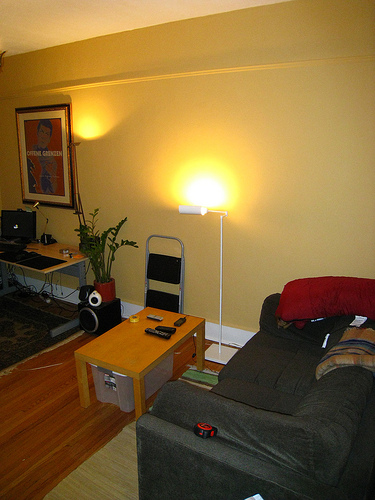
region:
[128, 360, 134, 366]
part of a table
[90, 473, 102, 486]
part of a carpet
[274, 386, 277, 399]
part of a pillow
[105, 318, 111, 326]
part of a speaker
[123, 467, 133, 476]
part of a floor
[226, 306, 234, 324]
part of a wall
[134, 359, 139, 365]
edge of a table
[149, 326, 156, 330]
part of a remote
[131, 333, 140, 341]
edge of a table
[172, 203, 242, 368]
a white floor lamp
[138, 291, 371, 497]
a dark grey couch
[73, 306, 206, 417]
a light brown table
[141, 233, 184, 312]
a folded up step ladder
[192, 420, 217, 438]
a black and red measuring tape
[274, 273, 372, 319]
a red throw pillow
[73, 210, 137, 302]
a green potted plant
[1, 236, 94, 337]
a light brown wooden desk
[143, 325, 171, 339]
a black remote control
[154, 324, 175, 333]
a black remote control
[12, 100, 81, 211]
Picture hanging on the wall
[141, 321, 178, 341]
Remote controllers of the TV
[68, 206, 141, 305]
A green planet in the room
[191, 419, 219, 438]
A red and black measuring tape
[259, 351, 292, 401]
Part of the couch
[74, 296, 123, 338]
A speaker on the ground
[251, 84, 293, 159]
Part of the wall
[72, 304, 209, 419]
A table in the room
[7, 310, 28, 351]
Part of the carpet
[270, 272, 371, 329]
A red blanket on the couch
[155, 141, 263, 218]
a light is shining on the wall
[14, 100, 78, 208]
a frame is hanging on the wall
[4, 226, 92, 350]
a table is against the wall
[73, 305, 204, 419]
a coffee table is in front of the couch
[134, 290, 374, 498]
the couch is made of cloth material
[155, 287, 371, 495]
the couch is black in color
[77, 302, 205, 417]
the table is made of wood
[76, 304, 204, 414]
the wood is brown in color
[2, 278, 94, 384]
a carpet is on the floor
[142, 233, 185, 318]
a folding step ladder is against the wall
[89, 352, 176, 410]
clear pplastic tote with white lid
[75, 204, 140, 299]
green plant in terra cotta colored pot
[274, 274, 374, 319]
large red pillow on the arm of the couch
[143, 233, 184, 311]
silver and black footstool folded against wall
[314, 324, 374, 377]
tan and blue plaid blanket folded on back of the couch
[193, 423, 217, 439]
black and red tape measure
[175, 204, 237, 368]
white stand up lamp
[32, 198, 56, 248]
silver desk lamp with black base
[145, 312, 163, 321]
grey remote on the coffee table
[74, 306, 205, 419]
light brown wooden coffee table